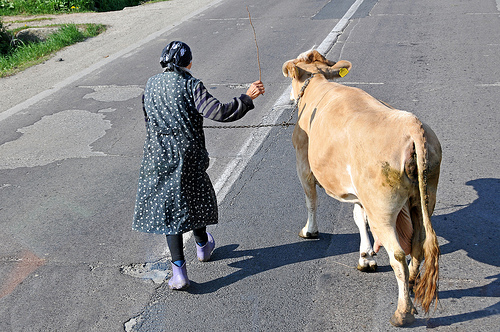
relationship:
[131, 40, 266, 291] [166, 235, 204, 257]
lady wearing socks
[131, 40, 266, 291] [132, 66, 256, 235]
lady wearing coat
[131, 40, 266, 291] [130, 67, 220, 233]
lady wearing dress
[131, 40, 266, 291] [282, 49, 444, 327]
lady walking cow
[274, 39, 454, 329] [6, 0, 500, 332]
cow walking down road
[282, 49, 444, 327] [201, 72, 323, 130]
cow wearing chain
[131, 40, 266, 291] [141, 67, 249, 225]
lady wearing coat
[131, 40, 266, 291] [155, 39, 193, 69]
lady wearing scarf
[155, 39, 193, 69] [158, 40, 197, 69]
scarf on head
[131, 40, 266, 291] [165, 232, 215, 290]
lady wearing boots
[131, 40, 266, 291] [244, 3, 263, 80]
lady holding stick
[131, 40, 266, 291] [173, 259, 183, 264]
lady wearing sock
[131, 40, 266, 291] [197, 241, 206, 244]
lady wearing sock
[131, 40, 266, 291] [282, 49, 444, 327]
lady with cow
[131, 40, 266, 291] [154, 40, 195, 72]
lady with bandana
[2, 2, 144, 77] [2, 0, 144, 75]
patch of grass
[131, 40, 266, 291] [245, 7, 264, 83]
lady holding stick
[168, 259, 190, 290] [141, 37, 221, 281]
boot of woman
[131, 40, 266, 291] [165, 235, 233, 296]
lady wearing shoes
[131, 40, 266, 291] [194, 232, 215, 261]
lady wearing boot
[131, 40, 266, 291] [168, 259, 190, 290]
lady wearing boot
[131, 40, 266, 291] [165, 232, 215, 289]
lady wearing shoes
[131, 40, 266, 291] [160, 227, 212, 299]
lady wearing shoes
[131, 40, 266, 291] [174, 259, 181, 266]
lady wearing sock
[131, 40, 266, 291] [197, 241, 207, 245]
lady wearing sock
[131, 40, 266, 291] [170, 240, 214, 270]
lady wearing socks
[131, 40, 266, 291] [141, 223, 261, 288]
lady wearing socks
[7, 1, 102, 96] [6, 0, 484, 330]
grass on side of road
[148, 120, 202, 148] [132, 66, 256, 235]
mid-section of coat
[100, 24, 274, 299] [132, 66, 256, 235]
lady wearing coat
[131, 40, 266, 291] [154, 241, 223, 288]
lady wearing gray sneakers